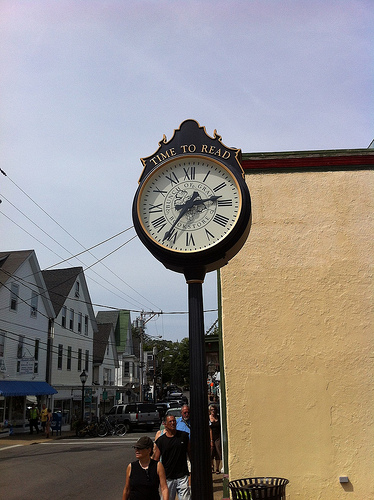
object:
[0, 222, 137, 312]
electrical line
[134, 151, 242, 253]
clock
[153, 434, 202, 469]
sleeveless black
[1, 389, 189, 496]
street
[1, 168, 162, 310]
powerline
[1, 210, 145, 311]
powerline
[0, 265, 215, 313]
powerline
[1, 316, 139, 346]
powerline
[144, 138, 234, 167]
wording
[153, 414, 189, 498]
man